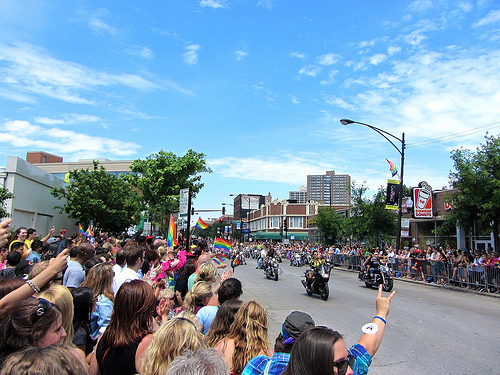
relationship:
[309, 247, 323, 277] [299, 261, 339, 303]
person on bike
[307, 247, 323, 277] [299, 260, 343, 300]
person riding motorcycle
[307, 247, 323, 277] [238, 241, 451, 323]
person in parade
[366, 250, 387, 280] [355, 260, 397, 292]
person riding motorbike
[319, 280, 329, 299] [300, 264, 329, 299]
tire on motorcycle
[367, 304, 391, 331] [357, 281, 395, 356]
bracelet on arm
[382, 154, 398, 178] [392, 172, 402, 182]
flag on pole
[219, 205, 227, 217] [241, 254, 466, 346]
light above street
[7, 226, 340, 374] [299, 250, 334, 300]
people watching motorcycle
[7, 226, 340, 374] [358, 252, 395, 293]
people watching motorcycle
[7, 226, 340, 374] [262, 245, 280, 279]
people watching motorcycle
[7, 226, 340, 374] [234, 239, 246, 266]
people watching motorcycle